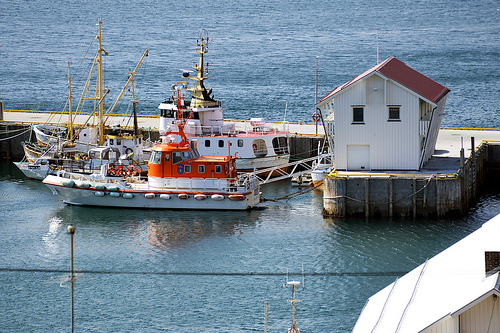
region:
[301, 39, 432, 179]
a white boat house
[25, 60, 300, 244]
two boats next to each other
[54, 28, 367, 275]
two boats next to each other on the water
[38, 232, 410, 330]
a body of water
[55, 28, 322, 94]
waves in the water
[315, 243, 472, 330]
a white roof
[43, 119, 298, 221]
orange boat on the water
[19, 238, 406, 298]
power lines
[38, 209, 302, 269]
reflection of two boats next to each other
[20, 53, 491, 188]
a dock on the water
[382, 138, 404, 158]
white siding on building.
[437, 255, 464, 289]
slanted roof on building.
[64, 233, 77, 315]
tall skinny pole near water.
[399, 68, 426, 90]
red roof of building.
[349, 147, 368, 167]
garage door on building.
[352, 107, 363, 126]
window on the building.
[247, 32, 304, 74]
water behind the pier.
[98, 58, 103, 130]
yellow pole on boat.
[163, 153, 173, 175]
door on the boat.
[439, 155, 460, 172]
shadow near the building.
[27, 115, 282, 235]
numerous boats are docked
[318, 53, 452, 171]
white house is next to boats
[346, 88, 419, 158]
white house has black windows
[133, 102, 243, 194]
orange engine room on white boat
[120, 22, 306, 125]
water across dock is fairly calm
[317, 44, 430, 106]
red roof on white dock house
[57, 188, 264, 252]
reflection from boats on calm water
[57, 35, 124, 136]
wooden mast for sail on boat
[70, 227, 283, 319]
water near boats is dark blue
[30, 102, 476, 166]
light grey pavement running near dock house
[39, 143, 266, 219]
red and white tug boat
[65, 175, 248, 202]
bumpers for boat docking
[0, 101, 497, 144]
the concrete pier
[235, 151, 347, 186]
ramp to board boat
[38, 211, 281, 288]
reflecdtion of boat in water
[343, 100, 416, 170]
two upstairs windows over a garage door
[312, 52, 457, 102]
red roof on white building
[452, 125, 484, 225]
two wood pilings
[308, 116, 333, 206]
small white with yellow boat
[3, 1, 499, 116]
ripples in the open sea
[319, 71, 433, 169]
building on the pier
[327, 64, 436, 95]
building has a red roof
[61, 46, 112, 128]
poles are yellow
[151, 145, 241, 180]
part of the boat is orange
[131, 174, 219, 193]
white railing along the boat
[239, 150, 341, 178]
portable walkway to boat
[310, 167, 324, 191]
boat is white and yellow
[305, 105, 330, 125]
float ring on the pole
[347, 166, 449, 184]
yellow railing along the pier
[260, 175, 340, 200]
rope tying the boat to the pier